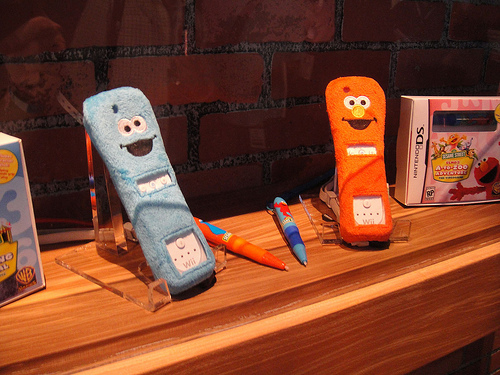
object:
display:
[1, 1, 499, 375]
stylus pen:
[271, 194, 308, 269]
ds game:
[394, 93, 499, 205]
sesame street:
[1, 0, 499, 374]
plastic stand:
[55, 128, 227, 315]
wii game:
[325, 75, 393, 241]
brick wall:
[2, 1, 498, 223]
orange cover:
[324, 73, 393, 242]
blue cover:
[81, 85, 216, 295]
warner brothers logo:
[14, 265, 36, 284]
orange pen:
[191, 216, 292, 271]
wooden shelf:
[0, 203, 498, 374]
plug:
[33, 211, 124, 245]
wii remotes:
[82, 85, 217, 296]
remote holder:
[298, 149, 411, 244]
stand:
[59, 123, 227, 312]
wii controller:
[323, 76, 394, 243]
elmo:
[446, 157, 498, 197]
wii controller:
[80, 84, 213, 291]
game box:
[0, 128, 48, 313]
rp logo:
[421, 183, 439, 201]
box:
[393, 94, 498, 204]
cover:
[82, 85, 216, 294]